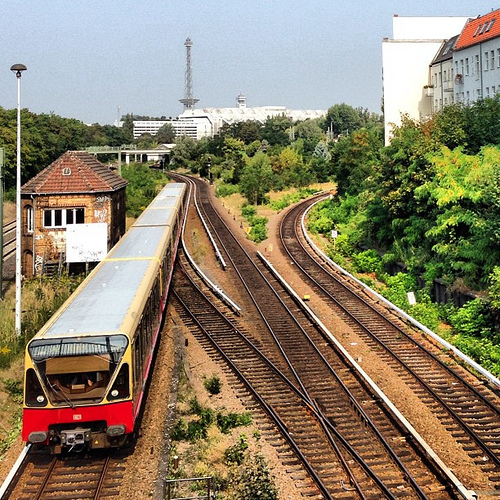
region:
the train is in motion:
[28, 137, 223, 492]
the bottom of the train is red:
[5, 392, 155, 457]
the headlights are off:
[12, 370, 138, 413]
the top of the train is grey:
[46, 190, 173, 350]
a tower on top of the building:
[152, 24, 215, 124]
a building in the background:
[106, 90, 311, 144]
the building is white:
[85, 75, 317, 160]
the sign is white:
[42, 206, 118, 270]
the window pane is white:
[32, 200, 88, 227]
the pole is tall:
[0, 57, 37, 327]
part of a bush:
[438, 199, 445, 208]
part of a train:
[195, 350, 197, 362]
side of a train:
[121, 391, 134, 411]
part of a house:
[108, 245, 130, 272]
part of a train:
[125, 358, 140, 398]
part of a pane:
[305, 337, 317, 354]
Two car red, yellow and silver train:
[22, 179, 189, 463]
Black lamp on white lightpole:
[9, 60, 27, 345]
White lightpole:
[14, 76, 23, 339]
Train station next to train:
[17, 147, 129, 282]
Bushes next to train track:
[308, 97, 498, 371]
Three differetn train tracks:
[162, 172, 498, 499]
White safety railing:
[253, 247, 480, 499]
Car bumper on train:
[104, 424, 125, 440]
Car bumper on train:
[26, 430, 47, 445]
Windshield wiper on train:
[42, 373, 77, 412]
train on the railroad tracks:
[19, 179, 187, 458]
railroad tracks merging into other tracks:
[167, 163, 497, 496]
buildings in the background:
[131, 5, 498, 170]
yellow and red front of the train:
[21, 333, 136, 443]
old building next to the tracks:
[22, 149, 129, 279]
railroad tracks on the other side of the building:
[1, 217, 23, 264]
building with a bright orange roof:
[454, 6, 498, 108]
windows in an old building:
[43, 206, 86, 228]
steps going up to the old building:
[40, 256, 62, 283]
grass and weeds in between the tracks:
[153, 330, 279, 497]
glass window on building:
[40, 205, 52, 228]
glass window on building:
[53, 208, 63, 227]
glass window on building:
[65, 207, 71, 224]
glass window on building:
[71, 206, 81, 221]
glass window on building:
[25, 205, 30, 235]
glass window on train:
[27, 355, 108, 410]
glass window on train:
[136, 316, 146, 352]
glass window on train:
[151, 280, 157, 320]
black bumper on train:
[105, 425, 122, 440]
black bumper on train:
[26, 427, 48, 449]